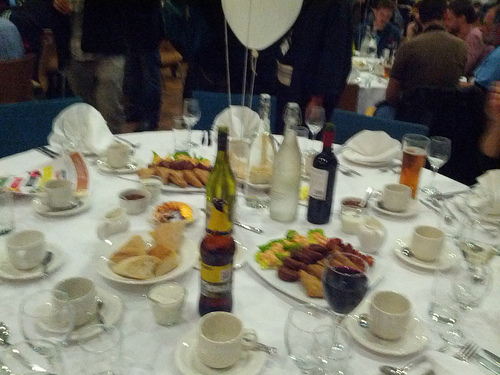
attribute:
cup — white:
[366, 297, 411, 335]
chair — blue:
[326, 106, 423, 147]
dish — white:
[95, 232, 195, 285]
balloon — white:
[223, 1, 303, 52]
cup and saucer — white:
[377, 179, 419, 219]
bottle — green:
[210, 123, 235, 237]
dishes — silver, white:
[315, 246, 478, 359]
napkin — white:
[347, 133, 401, 165]